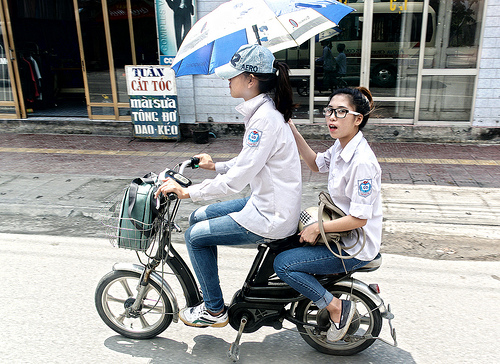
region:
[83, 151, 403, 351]
this is a scooter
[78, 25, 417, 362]
people riding a scooter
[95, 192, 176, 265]
basket on front of scooter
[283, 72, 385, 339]
this is a woman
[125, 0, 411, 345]
woman holding an umbrella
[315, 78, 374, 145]
woman has mouth open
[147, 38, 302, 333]
this is a person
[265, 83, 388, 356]
this is a person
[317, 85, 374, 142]
this is a person's head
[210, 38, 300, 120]
this is a person's head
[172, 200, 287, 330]
this is a person's leg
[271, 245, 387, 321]
this is a person's leg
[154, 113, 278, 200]
this is a person's hand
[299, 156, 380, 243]
this is a person's hand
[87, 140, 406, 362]
this is a bicycle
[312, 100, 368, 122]
this is a pair of glasses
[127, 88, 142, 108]
white letter on sign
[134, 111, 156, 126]
white letter on sign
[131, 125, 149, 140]
white letter on sign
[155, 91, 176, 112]
white letter on sign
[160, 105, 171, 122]
white letter on sign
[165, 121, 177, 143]
white letter on sign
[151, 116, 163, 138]
white letter on sign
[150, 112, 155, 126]
white letter on sign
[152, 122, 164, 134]
white letter on sign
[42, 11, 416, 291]
these are two women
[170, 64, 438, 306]
the woman are wearing white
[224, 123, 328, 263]
the shirt is white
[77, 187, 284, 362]
this is a scooter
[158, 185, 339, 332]
these are jeans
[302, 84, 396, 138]
the girl has glasses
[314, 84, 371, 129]
the glasses are white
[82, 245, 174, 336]
the tire is rubber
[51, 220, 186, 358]
the tire is black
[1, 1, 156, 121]
open sliding glass doors with gold frame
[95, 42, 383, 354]
sides of two women on scooter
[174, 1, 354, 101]
blue nd white umbrella over woman's head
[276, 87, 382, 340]
woman clutching purse with straps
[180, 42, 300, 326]
woman with ponytail in back of cap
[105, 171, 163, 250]
bag with strap in basket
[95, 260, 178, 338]
fender over scooter tire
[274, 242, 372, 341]
blue jeans on bent leg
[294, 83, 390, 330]
this is a person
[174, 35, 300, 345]
this is a person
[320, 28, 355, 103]
this is a person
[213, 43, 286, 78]
girl wearing a blue hat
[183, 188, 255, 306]
girl wearing blue jeans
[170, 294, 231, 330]
girl wearing white shoes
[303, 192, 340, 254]
girls holding a pocket book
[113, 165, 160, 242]
green bag on the bike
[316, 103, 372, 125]
girl wearing glasses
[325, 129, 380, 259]
girl wearing a white shirt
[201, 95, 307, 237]
girl wearing a white shirt